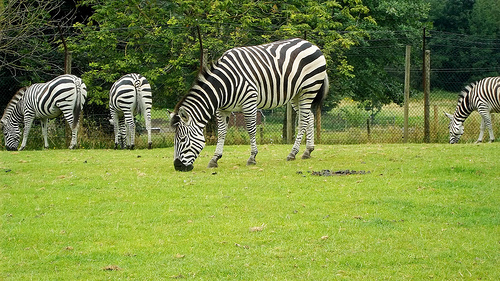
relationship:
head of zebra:
[166, 109, 206, 171] [141, 39, 428, 236]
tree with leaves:
[49, 0, 386, 111] [224, 5, 324, 30]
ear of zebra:
[175, 107, 197, 134] [163, 35, 340, 176]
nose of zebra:
[173, 158, 188, 173] [162, 31, 332, 172]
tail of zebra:
[133, 82, 144, 117] [163, 35, 340, 176]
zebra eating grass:
[0, 73, 88, 152] [2, 146, 483, 279]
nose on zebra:
[173, 158, 185, 171] [163, 35, 340, 176]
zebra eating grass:
[447, 71, 497, 145] [2, 146, 483, 279]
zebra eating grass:
[162, 31, 332, 172] [2, 146, 483, 279]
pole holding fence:
[399, 39, 435, 141] [337, 71, 432, 146]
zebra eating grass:
[8, 36, 478, 183] [321, 185, 339, 224]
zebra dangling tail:
[22, 72, 96, 131] [310, 71, 330, 115]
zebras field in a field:
[1, 36, 498, 191] [1, 148, 484, 279]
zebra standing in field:
[8, 36, 478, 183] [1, 141, 484, 267]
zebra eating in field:
[108, 72, 153, 149] [2, 1, 477, 273]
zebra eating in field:
[167, 37, 330, 173] [2, 1, 477, 273]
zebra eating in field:
[442, 77, 500, 145] [2, 1, 477, 273]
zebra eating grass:
[167, 37, 330, 173] [2, 146, 483, 279]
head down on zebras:
[166, 109, 206, 171] [1, 27, 373, 165]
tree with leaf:
[1, 2, 83, 82] [468, 39, 479, 49]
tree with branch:
[1, 2, 83, 82] [45, 1, 67, 18]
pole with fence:
[419, 47, 436, 141] [0, 22, 500, 149]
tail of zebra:
[73, 78, 80, 124] [3, 72, 88, 151]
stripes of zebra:
[228, 36, 320, 94] [126, 22, 360, 208]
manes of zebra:
[163, 76, 202, 116] [162, 31, 332, 172]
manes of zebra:
[163, 76, 202, 116] [447, 71, 497, 145]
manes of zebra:
[163, 76, 202, 116] [100, 70, 156, 148]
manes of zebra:
[163, 76, 202, 116] [3, 72, 88, 151]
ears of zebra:
[158, 104, 187, 125] [155, 34, 344, 209]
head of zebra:
[157, 105, 217, 197] [163, 27, 358, 194]